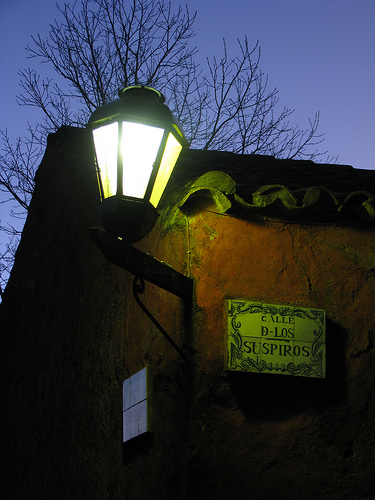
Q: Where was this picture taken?
A: Outside a building.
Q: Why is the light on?
A: It's dark.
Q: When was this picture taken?
A: At night.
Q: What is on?
A: The light.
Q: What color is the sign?
A: Green.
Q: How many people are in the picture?
A: None.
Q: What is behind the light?
A: A tree.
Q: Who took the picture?
A: The photographer.